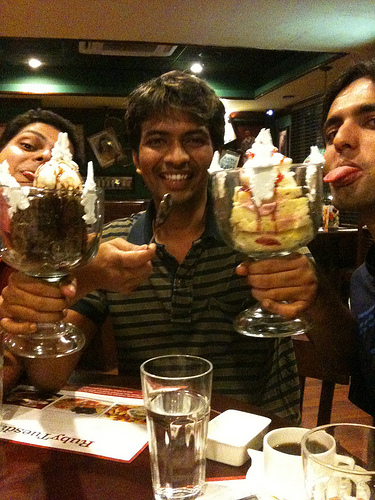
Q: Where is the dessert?
A: In cups.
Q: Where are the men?
A: Ruby Tuesdays.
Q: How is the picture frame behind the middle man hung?
A: Crookedly.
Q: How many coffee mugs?
A: 1.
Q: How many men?
A: 3.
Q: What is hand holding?
A: Ice cream dish.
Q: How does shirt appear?
A: Striped.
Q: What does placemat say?
A: Ruby tuesday.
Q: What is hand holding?
A: Spoon.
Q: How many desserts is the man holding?
A: Two.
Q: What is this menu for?
A: American restaurant.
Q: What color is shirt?
A: Green.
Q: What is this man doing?
A: Sticking tongue out.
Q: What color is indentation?
A: Green.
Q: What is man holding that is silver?
A: A spoon.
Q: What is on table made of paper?
A: Placemat with restaurant name.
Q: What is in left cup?
A: Chocolate dessert.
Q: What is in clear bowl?
A: A dessert.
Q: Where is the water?
A: In glass.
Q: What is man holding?
A: Bowl of dessert.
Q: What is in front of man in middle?
A: Hand holding a spoon.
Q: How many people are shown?
A: 3.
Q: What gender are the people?
A: Male.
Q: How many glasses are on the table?
A: 2.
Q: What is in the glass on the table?
A: Water.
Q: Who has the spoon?
A: Man in the middle.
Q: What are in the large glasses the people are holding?
A: Cake and ice cream.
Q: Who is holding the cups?
A: Middle man.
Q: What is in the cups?
A: Cake.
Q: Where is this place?
A: Restaurant.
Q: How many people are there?
A: 3.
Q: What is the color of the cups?
A: Colorless.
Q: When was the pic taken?
A: At night.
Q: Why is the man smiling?
A: He is happy.